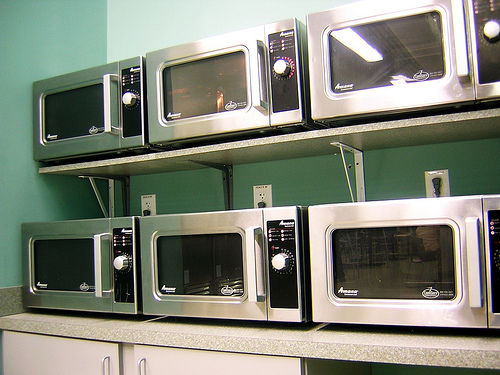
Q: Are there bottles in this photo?
A: No, there are no bottles.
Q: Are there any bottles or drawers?
A: No, there are no bottles or drawers.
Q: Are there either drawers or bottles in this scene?
A: No, there are no bottles or drawers.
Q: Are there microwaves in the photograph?
A: Yes, there is a microwave.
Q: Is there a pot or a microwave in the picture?
A: Yes, there is a microwave.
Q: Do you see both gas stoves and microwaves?
A: No, there is a microwave but no gas stoves.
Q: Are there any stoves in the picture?
A: No, there are no stoves.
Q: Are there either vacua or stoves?
A: No, there are no stoves or vacua.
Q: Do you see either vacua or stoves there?
A: No, there are no stoves or vacua.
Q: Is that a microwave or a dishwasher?
A: That is a microwave.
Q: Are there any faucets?
A: No, there are no faucets.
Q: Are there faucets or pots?
A: No, there are no faucets or pots.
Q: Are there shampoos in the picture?
A: No, there are no shampoos.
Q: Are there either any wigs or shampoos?
A: No, there are no shampoos or wigs.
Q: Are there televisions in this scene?
A: No, there are no televisions.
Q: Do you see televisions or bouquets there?
A: No, there are no televisions or bouquets.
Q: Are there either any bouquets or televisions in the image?
A: No, there are no televisions or bouquets.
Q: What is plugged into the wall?
A: The cords are plugged into the wall.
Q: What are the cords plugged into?
A: The cords are plugged into the wall.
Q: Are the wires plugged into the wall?
A: Yes, the wires are plugged into the wall.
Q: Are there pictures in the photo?
A: No, there are no pictures.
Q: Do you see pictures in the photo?
A: No, there are no pictures.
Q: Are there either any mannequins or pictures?
A: No, there are no pictures or mannequins.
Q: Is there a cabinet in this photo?
A: Yes, there is a cabinet.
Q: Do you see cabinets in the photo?
A: Yes, there is a cabinet.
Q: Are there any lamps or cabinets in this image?
A: Yes, there is a cabinet.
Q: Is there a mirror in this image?
A: No, there are no mirrors.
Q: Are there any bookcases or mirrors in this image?
A: No, there are no mirrors or bookcases.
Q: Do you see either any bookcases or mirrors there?
A: No, there are no mirrors or bookcases.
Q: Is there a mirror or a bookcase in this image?
A: No, there are no mirrors or bookcases.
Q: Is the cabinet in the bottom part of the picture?
A: Yes, the cabinet is in the bottom of the image.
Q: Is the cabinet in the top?
A: No, the cabinet is in the bottom of the image.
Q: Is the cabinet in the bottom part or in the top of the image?
A: The cabinet is in the bottom of the image.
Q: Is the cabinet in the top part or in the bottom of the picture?
A: The cabinet is in the bottom of the image.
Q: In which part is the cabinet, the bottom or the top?
A: The cabinet is in the bottom of the image.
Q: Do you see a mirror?
A: No, there are no mirrors.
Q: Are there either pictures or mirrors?
A: No, there are no mirrors or pictures.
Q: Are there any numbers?
A: Yes, there are numbers.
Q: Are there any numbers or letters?
A: Yes, there are numbers.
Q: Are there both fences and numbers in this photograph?
A: No, there are numbers but no fences.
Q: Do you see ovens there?
A: Yes, there is an oven.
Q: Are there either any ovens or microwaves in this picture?
A: Yes, there is an oven.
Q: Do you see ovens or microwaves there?
A: Yes, there is an oven.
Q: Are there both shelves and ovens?
A: Yes, there are both an oven and a shelf.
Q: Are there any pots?
A: No, there are no pots.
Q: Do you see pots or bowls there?
A: No, there are no pots or bowls.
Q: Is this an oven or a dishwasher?
A: This is an oven.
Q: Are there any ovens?
A: Yes, there is an oven.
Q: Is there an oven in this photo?
A: Yes, there is an oven.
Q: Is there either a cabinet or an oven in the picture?
A: Yes, there is an oven.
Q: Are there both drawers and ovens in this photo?
A: No, there is an oven but no drawers.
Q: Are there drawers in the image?
A: No, there are no drawers.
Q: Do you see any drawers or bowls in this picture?
A: No, there are no drawers or bowls.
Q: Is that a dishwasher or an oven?
A: That is an oven.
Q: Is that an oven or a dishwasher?
A: That is an oven.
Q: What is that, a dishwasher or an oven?
A: That is an oven.